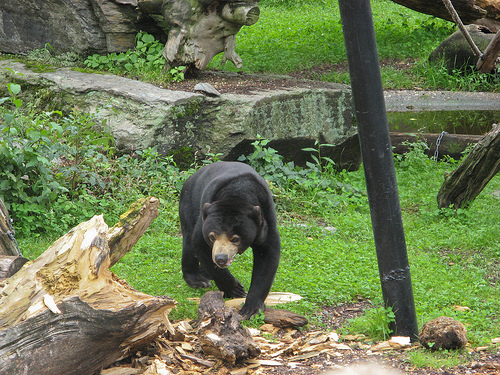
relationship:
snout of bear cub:
[210, 239, 235, 267] [180, 158, 290, 315]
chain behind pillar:
[433, 130, 447, 164] [337, 3, 418, 347]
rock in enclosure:
[24, 68, 352, 167] [3, 3, 490, 374]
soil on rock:
[163, 64, 326, 100] [24, 68, 352, 167]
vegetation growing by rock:
[8, 77, 164, 238] [24, 68, 352, 167]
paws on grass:
[180, 272, 259, 316] [23, 177, 500, 375]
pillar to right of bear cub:
[337, 3, 418, 347] [180, 158, 290, 315]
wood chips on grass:
[174, 306, 384, 373] [23, 177, 500, 375]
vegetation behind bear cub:
[8, 77, 164, 238] [180, 158, 290, 315]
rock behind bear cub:
[24, 68, 352, 167] [180, 158, 290, 315]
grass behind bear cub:
[205, 0, 490, 84] [180, 158, 290, 315]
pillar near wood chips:
[337, 3, 418, 347] [174, 306, 384, 373]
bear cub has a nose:
[180, 158, 290, 315] [215, 254, 228, 265]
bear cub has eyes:
[180, 158, 290, 315] [206, 229, 243, 246]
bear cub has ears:
[180, 158, 290, 315] [196, 199, 264, 224]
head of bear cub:
[201, 201, 258, 269] [180, 158, 290, 315]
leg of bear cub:
[247, 244, 279, 319] [180, 158, 290, 315]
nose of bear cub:
[215, 254, 228, 265] [180, 158, 290, 315]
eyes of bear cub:
[206, 229, 243, 246] [180, 158, 290, 315]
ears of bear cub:
[196, 199, 264, 224] [180, 158, 290, 315]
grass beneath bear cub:
[23, 177, 500, 375] [180, 158, 290, 315]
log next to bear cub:
[6, 203, 180, 375] [180, 158, 290, 315]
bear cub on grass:
[180, 158, 290, 315] [23, 177, 500, 375]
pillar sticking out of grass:
[337, 3, 418, 347] [23, 177, 500, 375]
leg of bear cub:
[199, 243, 242, 297] [180, 158, 290, 315]